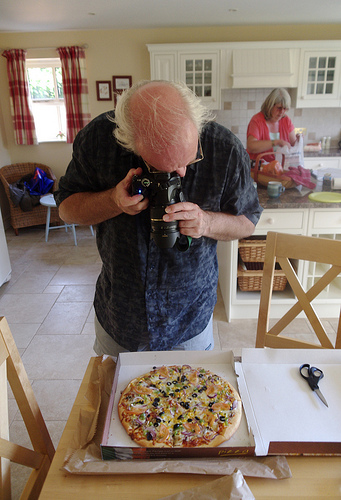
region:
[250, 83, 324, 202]
woman unpacking bag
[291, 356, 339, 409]
black handled scissors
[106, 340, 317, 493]
pizza in a box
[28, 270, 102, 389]
beige tile flooring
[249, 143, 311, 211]
woven picnic basket with red detail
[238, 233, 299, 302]
decorative basket on shelf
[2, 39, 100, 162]
red and white plaid curtains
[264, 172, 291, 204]
blue striped coffee mug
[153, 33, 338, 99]
white kitchen cabinets with glass fronts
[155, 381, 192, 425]
black oilves on pizza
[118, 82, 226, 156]
balding head of man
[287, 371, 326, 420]
scissors next to the pizza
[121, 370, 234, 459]
full pizza with toppings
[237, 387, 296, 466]
white pizza box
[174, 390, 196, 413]
olives on the pizza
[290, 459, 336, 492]
brown table next to box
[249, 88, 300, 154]
woman in the background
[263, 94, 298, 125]
woman wearing glasses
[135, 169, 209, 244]
camera pointed down at food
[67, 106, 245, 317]
shirt on the man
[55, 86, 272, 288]
man looking down into camera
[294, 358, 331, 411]
scissor with black handle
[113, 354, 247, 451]
pizza in cardboard box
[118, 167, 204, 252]
two hands on camera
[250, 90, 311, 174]
woman looking in plastic bag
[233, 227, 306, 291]
wicker baskets under drawer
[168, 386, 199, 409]
black olives on pizza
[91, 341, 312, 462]
open cardboard pizza box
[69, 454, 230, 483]
brown bag on table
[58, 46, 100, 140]
plaid curtains on window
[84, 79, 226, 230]
the man is bald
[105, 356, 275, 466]
the pizza in the box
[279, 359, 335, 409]
a pair of scissors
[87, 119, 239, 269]
he takes a picture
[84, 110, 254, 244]
he has glasses on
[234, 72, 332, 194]
the woman wears pink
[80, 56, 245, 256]
his hair is white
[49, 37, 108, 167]
the curtains are checkered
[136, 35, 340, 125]
kitchen cabinets are white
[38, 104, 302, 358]
his shirt is blue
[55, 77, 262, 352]
A balding man taking a photo of a pizza.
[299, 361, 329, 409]
A pair of scissors on the inside of a pizza box.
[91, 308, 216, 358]
Small shorts on a balding man.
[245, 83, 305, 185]
A white haired woman in a pink shirt.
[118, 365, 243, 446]
A loaded pizza in a box.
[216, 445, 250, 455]
The word Pizza on the side of a box.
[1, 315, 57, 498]
A light brown chair to the left of a pizza.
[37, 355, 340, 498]
A light brown table a pizza is sitting on.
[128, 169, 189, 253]
A large black camera a man is using.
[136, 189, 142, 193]
A blue light on a black camera.